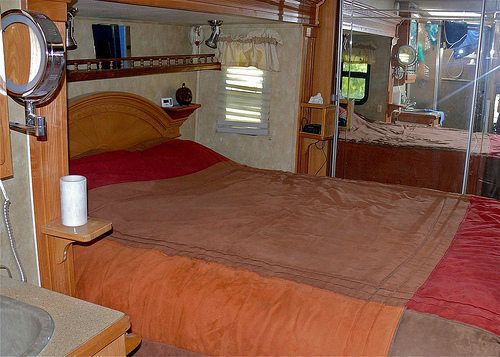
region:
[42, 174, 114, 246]
A white candle is on the shelf.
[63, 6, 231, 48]
Two lights are on the ceiling.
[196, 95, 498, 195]
The bed is reflected in the mirror.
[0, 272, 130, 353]
The sink is gray with a wood dege.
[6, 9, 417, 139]
The light over sink is reflected in mirror.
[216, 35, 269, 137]
The window is letting in sun.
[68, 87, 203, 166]
The headboard is wooden.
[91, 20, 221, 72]
Three books are on the shelf.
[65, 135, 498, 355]
The bed cover is multi color.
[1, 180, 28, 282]
A wire sticks out of the silver cable.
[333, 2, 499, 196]
room is reflected in the mirror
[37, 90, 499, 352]
bed is neatly made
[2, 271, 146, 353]
sink is empty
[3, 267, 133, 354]
sink countertop is clear of toiletries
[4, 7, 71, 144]
vanity mirror hangs over sink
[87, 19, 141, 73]
books sit on bookshelf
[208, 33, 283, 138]
shades are drawn on the window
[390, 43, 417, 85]
vanity mirror's reflection shows in other mirror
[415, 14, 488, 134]
reflection of the shower shows that it is empty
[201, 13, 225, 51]
light over the bed is turned off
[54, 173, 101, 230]
Candle on a stand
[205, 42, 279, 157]
curtain over a window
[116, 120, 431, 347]
blanket on a bed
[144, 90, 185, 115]
Clock on a shelf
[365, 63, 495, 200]
bed in the mirror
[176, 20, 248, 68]
lights over the bed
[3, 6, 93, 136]
Mirror on the wall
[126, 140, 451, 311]
brown blanket on bed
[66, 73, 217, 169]
Brown head board over bed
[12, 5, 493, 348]
Bedroom in a camper.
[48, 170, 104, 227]
A roll of white toilet paper.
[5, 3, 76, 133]
A round silver mirror.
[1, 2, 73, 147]
A retractable mirror.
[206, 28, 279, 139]
A small window.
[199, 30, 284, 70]
A beige topper on the window.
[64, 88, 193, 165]
A wooden headboard.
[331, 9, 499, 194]
Reflection of the room in a mirror.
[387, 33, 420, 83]
Reflection of a mirror in a mirror.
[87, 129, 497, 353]
A brown, red, and orange bedspread.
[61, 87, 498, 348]
A bed.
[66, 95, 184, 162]
A wooden headboard.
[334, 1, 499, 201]
Large mirror sliding doors.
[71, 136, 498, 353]
A red, orange, and brown bedspread.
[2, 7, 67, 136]
A round mirror attached to the wall.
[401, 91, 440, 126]
A reflection of a sink.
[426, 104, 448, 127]
A blue rag.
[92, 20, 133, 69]
Books.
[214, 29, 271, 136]
A small window with white blinds.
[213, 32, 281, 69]
A white and beige curtain.